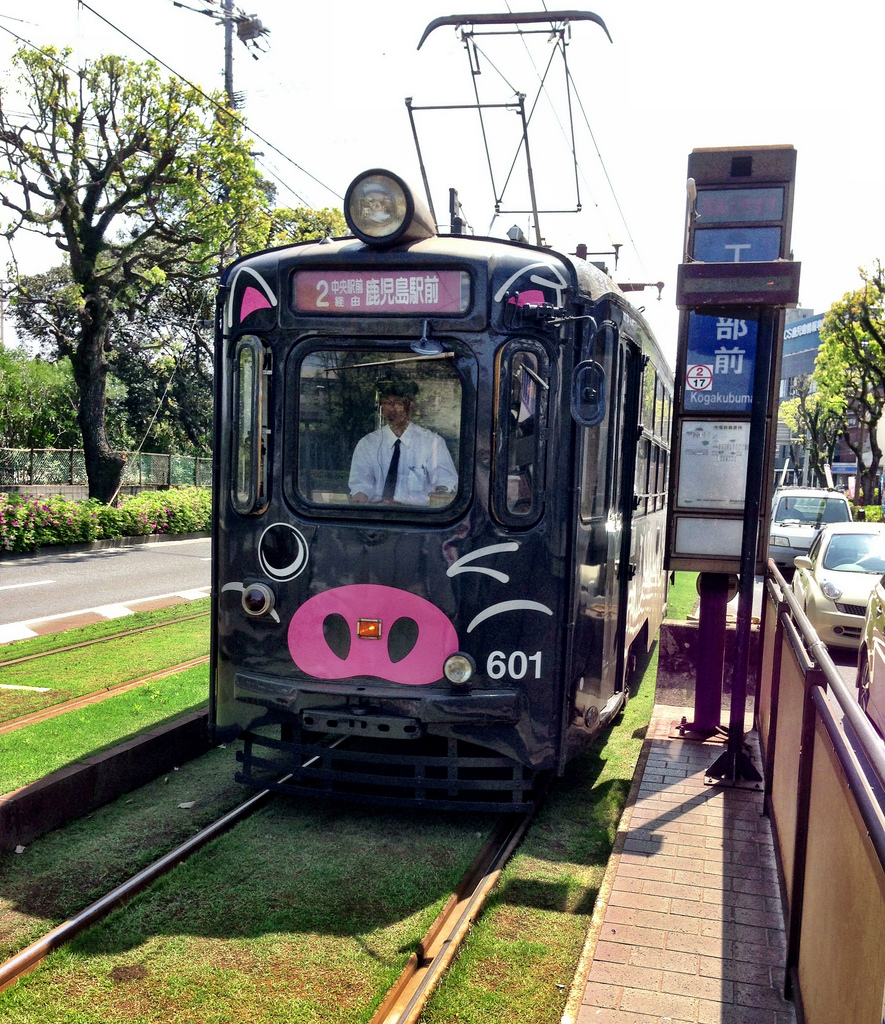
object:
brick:
[604, 906, 635, 926]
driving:
[348, 370, 459, 507]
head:
[372, 376, 419, 424]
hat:
[373, 369, 419, 399]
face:
[382, 396, 409, 425]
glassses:
[381, 398, 407, 406]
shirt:
[348, 421, 459, 507]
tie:
[382, 439, 402, 501]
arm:
[429, 435, 459, 487]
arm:
[348, 432, 375, 494]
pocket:
[408, 467, 425, 491]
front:
[209, 169, 605, 811]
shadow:
[0, 699, 723, 956]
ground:
[0, 533, 804, 1024]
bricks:
[589, 843, 771, 991]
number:
[529, 651, 541, 679]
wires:
[460, 28, 634, 245]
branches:
[0, 131, 159, 275]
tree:
[0, 53, 270, 507]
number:
[508, 651, 527, 679]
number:
[316, 279, 329, 306]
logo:
[288, 584, 458, 685]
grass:
[0, 560, 697, 1024]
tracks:
[0, 788, 534, 1024]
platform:
[561, 680, 801, 1024]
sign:
[664, 144, 797, 575]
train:
[208, 172, 674, 816]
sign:
[676, 416, 751, 509]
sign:
[683, 310, 757, 411]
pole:
[695, 571, 728, 733]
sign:
[675, 517, 755, 556]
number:
[487, 650, 506, 679]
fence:
[753, 556, 885, 1024]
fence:
[0, 447, 213, 486]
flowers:
[0, 485, 212, 551]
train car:
[208, 169, 674, 815]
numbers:
[487, 650, 542, 679]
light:
[344, 169, 414, 245]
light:
[443, 652, 473, 685]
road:
[0, 531, 213, 648]